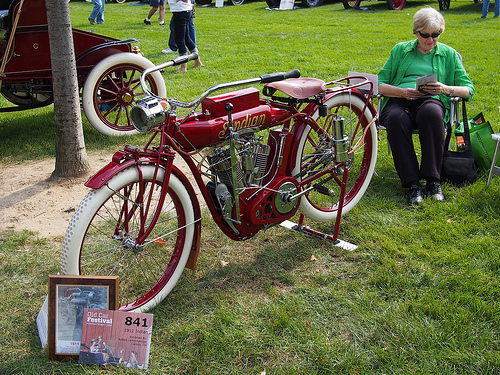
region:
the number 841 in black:
[124, 311, 147, 330]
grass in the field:
[265, 298, 484, 358]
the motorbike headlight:
[124, 97, 162, 131]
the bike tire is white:
[55, 175, 193, 307]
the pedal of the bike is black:
[280, 185, 330, 201]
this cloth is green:
[380, 42, 468, 92]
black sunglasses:
[413, 30, 439, 40]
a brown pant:
[386, 97, 442, 187]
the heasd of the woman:
[411, 8, 438, 46]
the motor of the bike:
[202, 142, 267, 186]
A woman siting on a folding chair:
[375, 5, 475, 207]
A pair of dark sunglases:
[414, 28, 441, 38]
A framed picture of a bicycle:
[47, 275, 118, 360]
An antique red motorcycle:
[64, 53, 381, 320]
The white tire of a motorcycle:
[61, 156, 201, 321]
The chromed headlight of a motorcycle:
[129, 96, 164, 133]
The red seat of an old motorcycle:
[262, 75, 325, 100]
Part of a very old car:
[0, 0, 170, 137]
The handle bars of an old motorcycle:
[139, 51, 299, 106]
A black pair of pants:
[381, 97, 447, 184]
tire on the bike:
[46, 164, 199, 309]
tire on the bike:
[292, 86, 377, 230]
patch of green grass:
[379, 273, 412, 311]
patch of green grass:
[272, 327, 315, 368]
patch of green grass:
[421, 308, 462, 353]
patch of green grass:
[441, 254, 468, 293]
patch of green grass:
[239, 322, 270, 362]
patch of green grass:
[426, 229, 471, 277]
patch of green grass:
[387, 222, 412, 245]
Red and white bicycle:
[57, 58, 384, 330]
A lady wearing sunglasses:
[401, 5, 453, 57]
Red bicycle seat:
[259, 63, 329, 111]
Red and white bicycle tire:
[47, 164, 205, 326]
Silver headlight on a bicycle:
[120, 96, 166, 136]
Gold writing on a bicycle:
[207, 111, 274, 136]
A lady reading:
[370, 6, 477, 136]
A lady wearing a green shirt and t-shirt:
[370, 9, 480, 126]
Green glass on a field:
[209, 10, 379, 65]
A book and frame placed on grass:
[22, 272, 161, 373]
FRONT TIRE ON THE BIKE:
[36, 137, 226, 334]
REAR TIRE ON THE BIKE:
[291, 83, 385, 231]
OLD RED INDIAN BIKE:
[37, 49, 419, 326]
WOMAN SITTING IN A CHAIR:
[372, 25, 484, 214]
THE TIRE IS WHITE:
[46, 172, 207, 334]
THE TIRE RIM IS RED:
[275, 78, 396, 245]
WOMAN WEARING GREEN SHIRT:
[370, 35, 481, 107]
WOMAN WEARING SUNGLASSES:
[408, 26, 453, 46]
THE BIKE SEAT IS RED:
[250, 62, 337, 117]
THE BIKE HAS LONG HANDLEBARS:
[115, 43, 326, 124]